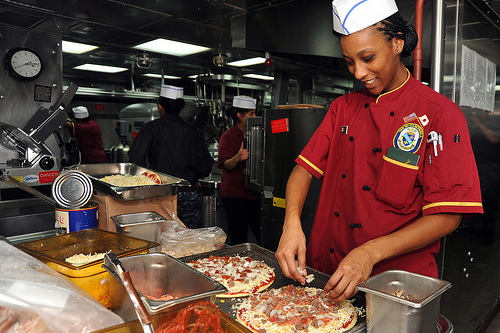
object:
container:
[356, 269, 453, 331]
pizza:
[236, 286, 358, 332]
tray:
[173, 243, 368, 332]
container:
[13, 229, 161, 311]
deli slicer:
[1, 83, 81, 189]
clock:
[4, 47, 44, 82]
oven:
[242, 109, 329, 246]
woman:
[275, 0, 484, 279]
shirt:
[294, 67, 484, 279]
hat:
[332, 0, 398, 36]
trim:
[422, 202, 482, 210]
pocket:
[374, 155, 419, 209]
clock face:
[11, 50, 41, 77]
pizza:
[185, 256, 276, 298]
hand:
[237, 142, 248, 161]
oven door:
[243, 117, 265, 192]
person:
[127, 85, 214, 227]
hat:
[160, 85, 184, 100]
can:
[51, 170, 99, 237]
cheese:
[66, 250, 112, 263]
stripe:
[342, 0, 367, 26]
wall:
[0, 24, 63, 170]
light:
[130, 38, 211, 57]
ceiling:
[0, 0, 286, 92]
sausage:
[295, 324, 303, 330]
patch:
[392, 123, 424, 154]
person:
[218, 95, 263, 245]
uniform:
[217, 126, 264, 198]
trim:
[298, 155, 324, 175]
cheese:
[296, 267, 315, 283]